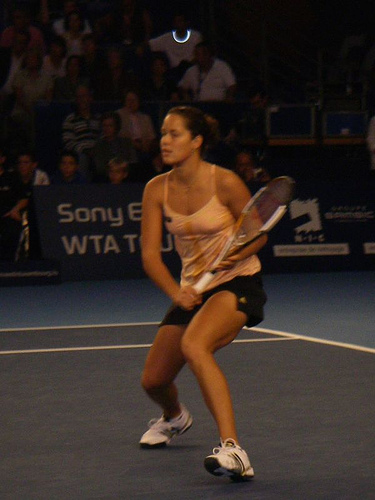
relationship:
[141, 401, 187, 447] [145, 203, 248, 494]
shoe on tennis player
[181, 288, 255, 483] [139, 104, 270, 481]
leg of player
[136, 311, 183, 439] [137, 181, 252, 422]
leg of tennis player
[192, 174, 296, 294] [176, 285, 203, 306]
racket in hand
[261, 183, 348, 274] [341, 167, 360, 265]
sponsor logo on wall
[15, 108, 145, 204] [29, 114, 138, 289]
spectator in stand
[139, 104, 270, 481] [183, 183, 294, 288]
player holding racket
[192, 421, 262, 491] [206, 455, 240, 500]
leg  raised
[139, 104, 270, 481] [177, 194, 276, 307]
player playing tennis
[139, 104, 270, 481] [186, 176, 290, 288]
player playing tennis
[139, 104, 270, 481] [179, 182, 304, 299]
player playing tennis